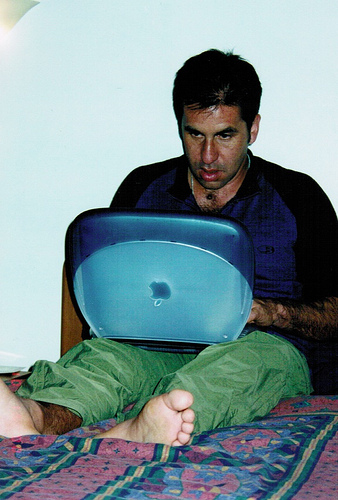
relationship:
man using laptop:
[0, 47, 337, 447] [68, 208, 255, 343]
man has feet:
[0, 47, 337, 447] [0, 375, 196, 448]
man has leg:
[0, 47, 337, 447] [30, 394, 83, 436]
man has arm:
[0, 47, 337, 447] [250, 293, 337, 342]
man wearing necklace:
[0, 47, 337, 447] [187, 148, 251, 192]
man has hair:
[0, 47, 337, 447] [172, 49, 264, 142]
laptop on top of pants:
[68, 208, 255, 343] [14, 330, 313, 435]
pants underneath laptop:
[14, 330, 313, 435] [68, 208, 255, 343]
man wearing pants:
[0, 47, 337, 447] [14, 330, 313, 435]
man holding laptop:
[0, 47, 337, 447] [68, 208, 255, 343]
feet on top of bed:
[0, 375, 196, 448] [1, 369, 338, 499]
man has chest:
[0, 47, 337, 447] [193, 185, 229, 215]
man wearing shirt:
[0, 47, 337, 447] [107, 147, 337, 355]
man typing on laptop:
[0, 47, 337, 447] [68, 208, 255, 343]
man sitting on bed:
[0, 47, 337, 447] [1, 369, 338, 499]